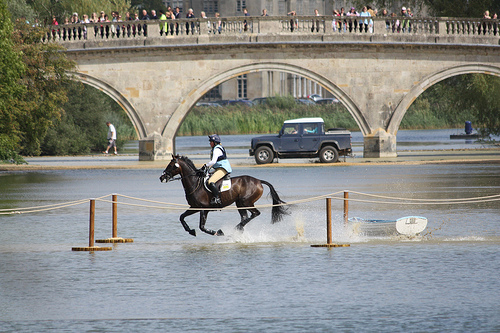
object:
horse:
[159, 153, 298, 235]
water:
[2, 166, 492, 327]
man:
[200, 133, 233, 206]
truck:
[250, 118, 355, 165]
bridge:
[13, 12, 496, 160]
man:
[105, 121, 118, 153]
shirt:
[110, 124, 116, 137]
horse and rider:
[160, 133, 298, 237]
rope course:
[0, 193, 497, 216]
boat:
[348, 210, 429, 238]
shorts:
[107, 137, 116, 145]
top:
[280, 115, 324, 122]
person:
[397, 7, 410, 31]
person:
[288, 9, 298, 31]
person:
[481, 8, 491, 33]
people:
[185, 9, 197, 35]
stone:
[140, 133, 173, 159]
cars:
[194, 95, 224, 109]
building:
[139, 0, 437, 100]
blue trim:
[348, 214, 430, 223]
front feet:
[185, 227, 198, 237]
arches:
[162, 48, 399, 157]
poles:
[72, 197, 114, 252]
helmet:
[208, 131, 221, 145]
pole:
[310, 196, 350, 248]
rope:
[1, 195, 499, 215]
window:
[283, 123, 301, 133]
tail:
[259, 177, 296, 226]